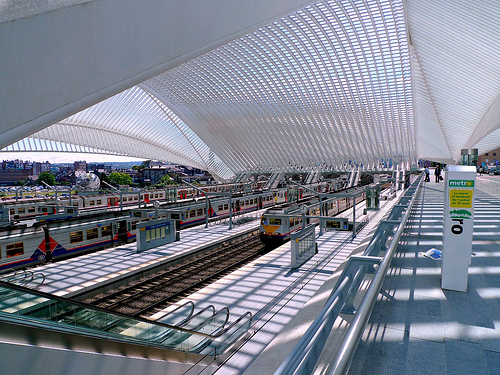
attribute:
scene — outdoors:
[241, 296, 393, 354]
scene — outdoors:
[303, 359, 425, 371]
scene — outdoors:
[295, 353, 419, 363]